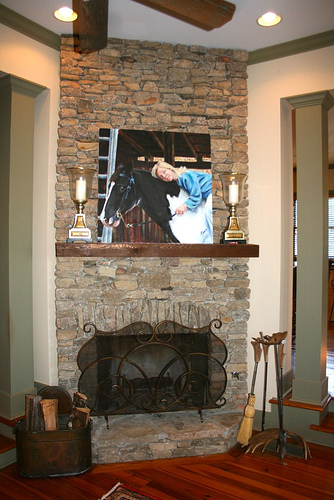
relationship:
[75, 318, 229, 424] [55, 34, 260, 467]
cover in front of fireplace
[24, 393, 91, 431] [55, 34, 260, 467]
logs for fireplace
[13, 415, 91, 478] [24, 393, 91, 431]
container holding logs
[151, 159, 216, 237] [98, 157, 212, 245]
woman on horse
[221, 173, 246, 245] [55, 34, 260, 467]
candleholder on fireplace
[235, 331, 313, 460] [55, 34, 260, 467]
tools for fireplace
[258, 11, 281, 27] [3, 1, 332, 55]
light in ceiling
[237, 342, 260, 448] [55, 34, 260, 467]
broom for fireplace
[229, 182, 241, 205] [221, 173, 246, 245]
candle in candleholder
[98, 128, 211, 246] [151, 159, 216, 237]
picture of woman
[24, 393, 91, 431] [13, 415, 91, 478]
logs are in container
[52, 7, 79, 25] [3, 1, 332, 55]
light on ceiling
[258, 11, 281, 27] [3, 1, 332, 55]
light on ceiling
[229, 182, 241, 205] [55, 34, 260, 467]
candle on top of fireplace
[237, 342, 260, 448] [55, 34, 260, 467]
broom next to fireplace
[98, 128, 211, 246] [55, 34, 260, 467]
picture over fireplace